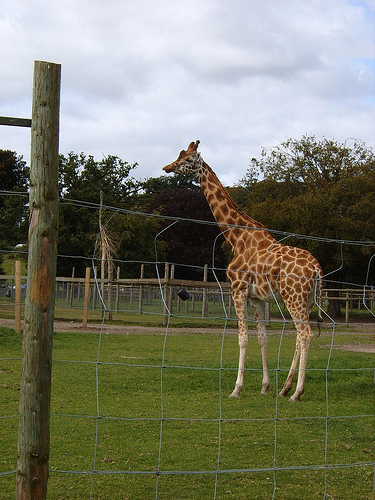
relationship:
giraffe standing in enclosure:
[162, 138, 324, 401] [38, 50, 371, 487]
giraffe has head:
[162, 138, 324, 401] [159, 134, 203, 181]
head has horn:
[159, 134, 203, 181] [184, 137, 193, 150]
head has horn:
[159, 134, 203, 181] [193, 135, 199, 153]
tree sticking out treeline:
[237, 129, 374, 184] [2, 151, 370, 279]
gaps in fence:
[95, 361, 164, 418] [6, 189, 374, 498]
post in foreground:
[12, 47, 67, 497] [51, 298, 370, 495]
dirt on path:
[57, 325, 68, 331] [50, 318, 366, 337]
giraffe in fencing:
[162, 138, 324, 401] [60, 260, 371, 324]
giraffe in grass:
[162, 138, 324, 401] [78, 385, 369, 461]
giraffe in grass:
[162, 138, 324, 401] [100, 410, 343, 482]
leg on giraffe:
[288, 311, 311, 401] [162, 138, 324, 401]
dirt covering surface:
[0, 301, 375, 355] [0, 292, 362, 495]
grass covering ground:
[151, 335, 186, 357] [98, 332, 346, 498]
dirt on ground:
[1, 310, 347, 338] [1, 296, 373, 499]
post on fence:
[12, 47, 67, 497] [0, 59, 374, 498]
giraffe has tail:
[162, 138, 324, 401] [312, 260, 324, 340]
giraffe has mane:
[162, 138, 324, 401] [195, 155, 252, 248]